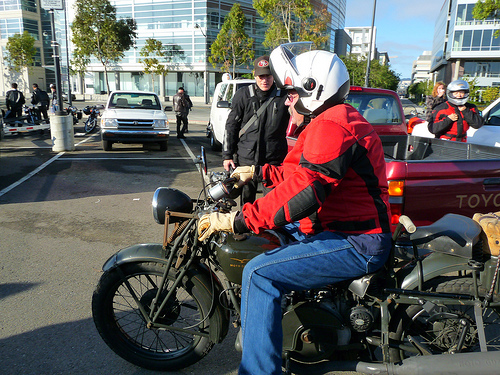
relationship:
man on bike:
[279, 54, 392, 267] [90, 187, 481, 363]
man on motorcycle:
[279, 54, 392, 267] [90, 187, 481, 363]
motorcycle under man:
[90, 187, 481, 363] [279, 54, 392, 267]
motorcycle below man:
[90, 187, 481, 363] [279, 54, 392, 267]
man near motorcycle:
[236, 57, 284, 161] [90, 187, 481, 363]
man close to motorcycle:
[236, 57, 284, 161] [90, 187, 481, 363]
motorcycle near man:
[90, 187, 481, 363] [236, 57, 284, 161]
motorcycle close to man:
[90, 187, 481, 363] [236, 57, 284, 161]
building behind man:
[3, 1, 352, 88] [236, 57, 284, 161]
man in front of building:
[236, 57, 284, 161] [3, 1, 352, 88]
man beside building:
[236, 57, 284, 161] [3, 1, 352, 88]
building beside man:
[3, 1, 352, 88] [236, 57, 284, 161]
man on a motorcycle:
[236, 57, 284, 161] [90, 187, 481, 363]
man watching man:
[236, 57, 284, 161] [279, 54, 392, 267]